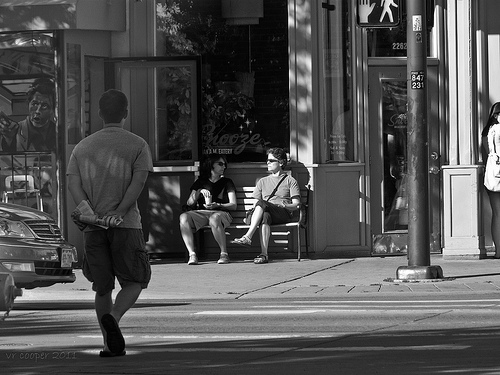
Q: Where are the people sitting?
A: Bench.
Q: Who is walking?
A: Man.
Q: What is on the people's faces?
A: Sunglasses.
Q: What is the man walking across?
A: Street.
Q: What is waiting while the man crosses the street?
A: Cars.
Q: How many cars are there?
A: One.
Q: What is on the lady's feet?
A: Sandals.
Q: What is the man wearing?
A: Shorts.